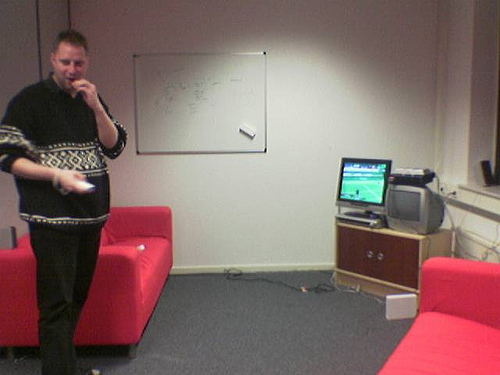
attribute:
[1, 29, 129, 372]
man — eating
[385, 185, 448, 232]
televison — off, black, gray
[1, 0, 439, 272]
wall — white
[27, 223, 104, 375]
pants — black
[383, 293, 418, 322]
wii — white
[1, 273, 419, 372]
floor — gray, carpeted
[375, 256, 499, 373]
couch — red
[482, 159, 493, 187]
speaker — black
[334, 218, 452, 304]
cabinet — brown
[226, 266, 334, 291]
cord — black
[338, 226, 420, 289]
door — brown, wood